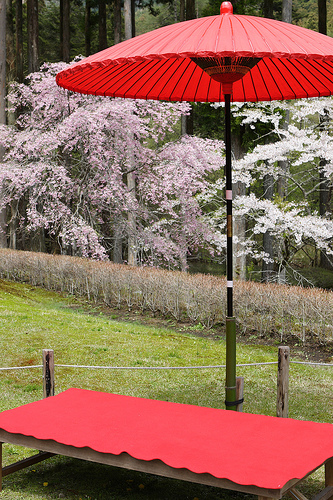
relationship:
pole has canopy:
[216, 84, 237, 411] [52, 1, 333, 108]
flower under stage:
[139, 484, 145, 491] [4, 381, 333, 498]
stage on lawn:
[4, 381, 333, 498] [1, 273, 332, 498]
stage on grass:
[4, 381, 333, 498] [0, 274, 330, 495]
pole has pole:
[216, 84, 237, 411] [216, 84, 237, 411]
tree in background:
[59, 0, 85, 60] [0, 6, 332, 301]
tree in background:
[123, 1, 138, 38] [0, 6, 332, 301]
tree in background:
[26, 2, 39, 79] [0, 6, 332, 301]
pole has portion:
[216, 84, 237, 411] [223, 313, 241, 408]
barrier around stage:
[2, 339, 332, 473] [4, 381, 333, 498]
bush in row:
[191, 271, 222, 331] [0, 247, 332, 348]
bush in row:
[0, 245, 333, 348] [0, 247, 332, 348]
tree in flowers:
[1, 53, 235, 271] [2, 49, 227, 244]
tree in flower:
[228, 94, 333, 285] [259, 177, 263, 180]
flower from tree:
[259, 177, 263, 180] [228, 94, 333, 285]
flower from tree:
[321, 166, 332, 178] [228, 94, 333, 285]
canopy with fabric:
[52, 1, 333, 108] [54, 16, 332, 102]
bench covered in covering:
[4, 381, 333, 498] [0, 385, 333, 493]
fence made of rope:
[3, 344, 332, 473] [1, 359, 331, 373]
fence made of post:
[3, 344, 332, 473] [276, 344, 294, 419]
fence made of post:
[3, 344, 332, 473] [41, 350, 59, 394]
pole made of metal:
[216, 84, 237, 411] [223, 93, 239, 409]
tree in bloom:
[1, 53, 235, 271] [2, 49, 227, 244]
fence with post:
[3, 344, 332, 473] [276, 344, 294, 419]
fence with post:
[3, 344, 332, 473] [41, 350, 59, 394]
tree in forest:
[123, 1, 138, 38] [2, 2, 332, 127]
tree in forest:
[59, 0, 85, 60] [2, 2, 332, 127]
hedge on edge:
[2, 244, 333, 348] [0, 277, 333, 359]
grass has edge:
[0, 274, 330, 495] [0, 277, 333, 359]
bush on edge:
[0, 245, 333, 348] [0, 277, 333, 359]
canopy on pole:
[52, 1, 333, 108] [216, 84, 237, 411]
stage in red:
[0, 383, 333, 500] [0, 385, 332, 490]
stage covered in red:
[0, 383, 333, 500] [0, 385, 332, 490]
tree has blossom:
[228, 94, 333, 285] [258, 226, 270, 236]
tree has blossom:
[228, 94, 333, 285] [289, 161, 306, 168]